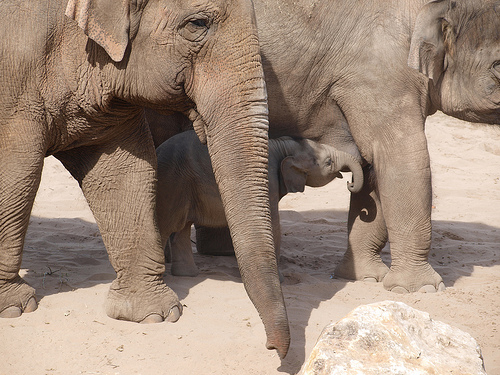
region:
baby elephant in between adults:
[123, 101, 453, 271]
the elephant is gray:
[16, 8, 353, 340]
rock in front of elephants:
[276, 251, 461, 365]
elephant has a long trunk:
[157, 44, 358, 369]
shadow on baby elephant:
[125, 76, 350, 242]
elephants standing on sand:
[42, 226, 299, 369]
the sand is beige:
[15, 250, 334, 355]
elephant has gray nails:
[82, 275, 207, 351]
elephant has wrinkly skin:
[64, 91, 362, 315]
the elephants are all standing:
[10, 13, 470, 373]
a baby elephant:
[276, 133, 361, 186]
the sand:
[48, 322, 192, 365]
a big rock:
[318, 320, 472, 374]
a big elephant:
[6, 9, 272, 177]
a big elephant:
[291, 18, 485, 137]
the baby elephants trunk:
[333, 150, 372, 195]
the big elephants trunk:
[207, 115, 305, 367]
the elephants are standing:
[14, 2, 491, 312]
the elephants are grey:
[8, 11, 499, 282]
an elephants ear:
[65, 3, 137, 57]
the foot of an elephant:
[101, 271, 188, 331]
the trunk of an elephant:
[196, 90, 310, 365]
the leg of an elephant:
[59, 120, 175, 285]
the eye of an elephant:
[183, 8, 219, 33]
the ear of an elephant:
[63, 0, 145, 65]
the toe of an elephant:
[136, 305, 164, 330]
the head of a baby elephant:
[276, 134, 371, 199]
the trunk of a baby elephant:
[338, 150, 366, 195]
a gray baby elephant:
[151, 125, 368, 282]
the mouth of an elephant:
[173, 71, 214, 146]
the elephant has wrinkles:
[22, 36, 303, 175]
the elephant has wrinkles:
[69, 16, 349, 276]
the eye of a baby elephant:
[321, 154, 336, 169]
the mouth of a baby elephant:
[333, 166, 347, 178]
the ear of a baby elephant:
[279, 152, 314, 196]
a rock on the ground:
[304, 296, 486, 373]